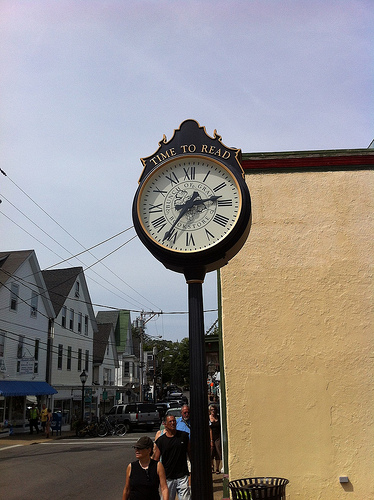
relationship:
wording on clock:
[144, 138, 234, 167] [125, 135, 260, 256]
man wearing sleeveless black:
[153, 414, 189, 498] [153, 434, 202, 469]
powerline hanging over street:
[1, 168, 162, 310] [1, 389, 189, 496]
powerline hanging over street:
[1, 210, 145, 311] [1, 389, 189, 496]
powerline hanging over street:
[0, 265, 215, 313] [1, 389, 189, 496]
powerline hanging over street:
[1, 316, 139, 346] [1, 389, 189, 496]